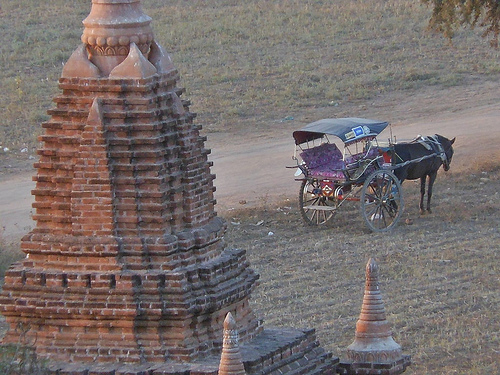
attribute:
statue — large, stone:
[7, 7, 416, 371]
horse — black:
[383, 133, 453, 215]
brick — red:
[70, 128, 105, 164]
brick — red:
[82, 120, 111, 137]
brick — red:
[35, 126, 73, 156]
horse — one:
[380, 126, 453, 216]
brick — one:
[84, 118, 106, 142]